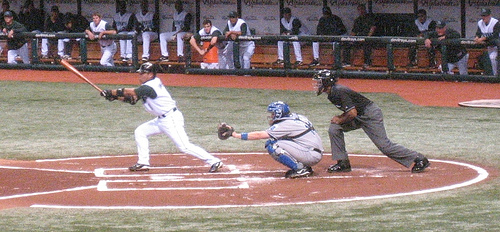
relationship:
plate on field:
[148, 168, 186, 184] [0, 56, 498, 231]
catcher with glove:
[258, 101, 322, 176] [212, 123, 238, 141]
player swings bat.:
[117, 58, 227, 175] [53, 60, 116, 98]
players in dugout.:
[3, 9, 496, 75] [0, 0, 499, 77]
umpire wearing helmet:
[317, 76, 431, 175] [314, 68, 335, 88]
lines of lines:
[0, 144, 489, 210] [0, 151, 489, 210]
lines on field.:
[0, 144, 489, 210] [0, 56, 498, 231]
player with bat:
[117, 58, 227, 175] [53, 60, 116, 98]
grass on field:
[1, 81, 497, 226] [0, 56, 498, 231]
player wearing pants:
[117, 58, 227, 175] [132, 109, 215, 174]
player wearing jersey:
[117, 58, 227, 175] [142, 78, 177, 119]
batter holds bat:
[113, 66, 223, 170] [53, 60, 116, 98]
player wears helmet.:
[117, 58, 227, 175] [138, 59, 158, 71]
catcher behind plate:
[258, 101, 322, 176] [148, 168, 186, 184]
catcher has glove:
[258, 101, 322, 176] [218, 124, 234, 140]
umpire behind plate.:
[317, 76, 431, 175] [148, 168, 186, 184]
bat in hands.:
[53, 60, 116, 98] [101, 87, 119, 106]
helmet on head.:
[137, 60, 156, 76] [135, 57, 157, 84]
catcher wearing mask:
[258, 101, 322, 176] [266, 102, 293, 124]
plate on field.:
[148, 168, 186, 184] [0, 56, 498, 231]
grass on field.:
[1, 81, 497, 226] [0, 56, 498, 231]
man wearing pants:
[317, 76, 431, 175] [330, 106, 416, 168]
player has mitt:
[258, 101, 322, 176] [212, 123, 238, 141]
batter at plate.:
[113, 66, 223, 170] [148, 168, 186, 184]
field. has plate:
[0, 56, 498, 231] [148, 168, 186, 184]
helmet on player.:
[137, 60, 156, 76] [117, 58, 227, 175]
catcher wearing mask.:
[258, 101, 322, 176] [266, 102, 293, 124]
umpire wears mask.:
[317, 76, 431, 175] [313, 71, 335, 97]